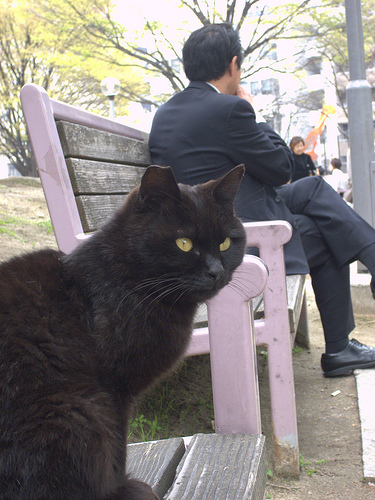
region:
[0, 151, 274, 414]
Black cat with green eyes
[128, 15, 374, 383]
Man in a suit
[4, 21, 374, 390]
Main sitting on a bench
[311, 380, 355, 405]
Cigarette butt on the ground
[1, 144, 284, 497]
Cat sitting on wooden platform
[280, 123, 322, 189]
Woman wearing a black coat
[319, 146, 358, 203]
Woman wearing a white coat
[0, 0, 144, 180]
Tree with green leaves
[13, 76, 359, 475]
Pink bench at the park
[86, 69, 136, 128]
Clear street light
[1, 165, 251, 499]
cat sitting on bench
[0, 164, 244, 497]
large cat sitting on bench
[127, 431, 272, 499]
part of wooden bench where cat is sitting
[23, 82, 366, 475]
bench where man is sitting on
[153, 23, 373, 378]
man sitting on bench outside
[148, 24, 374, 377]
man wearing suit sitting on bench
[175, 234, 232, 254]
green eyes of cat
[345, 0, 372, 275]
long gray pole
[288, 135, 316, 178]
woman wearing black in the distance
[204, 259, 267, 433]
pink arm of the bench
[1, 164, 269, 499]
a black cat sitting atop a pink and grey bench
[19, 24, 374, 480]
a businessman sitting on a pink and grey park bench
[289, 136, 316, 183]
a woman with a black top standing in the distance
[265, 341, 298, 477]
pink painted bench leg with rusty bottom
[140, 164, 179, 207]
black right ear is alert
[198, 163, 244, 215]
black left ear is alert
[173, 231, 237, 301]
cat face with intently looking eyes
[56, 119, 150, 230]
back of park bench looks weathered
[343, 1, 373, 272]
tall grey metal lamp post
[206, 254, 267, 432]
pale pink metal park bench arm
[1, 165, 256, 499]
a black cat on a bench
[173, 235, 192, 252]
eye of a cat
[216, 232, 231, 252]
eye of a cat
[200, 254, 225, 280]
nose of a cat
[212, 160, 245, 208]
ear of a black cat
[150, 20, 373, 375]
a man sitting at a bench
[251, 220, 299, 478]
pink wooden post on a bench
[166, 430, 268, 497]
wooden slat on bench seat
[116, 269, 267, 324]
a cat's whiskers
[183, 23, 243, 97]
back of a man's head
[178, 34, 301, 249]
A man sitting on the bench.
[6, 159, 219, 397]
Black cat sitting on the bench.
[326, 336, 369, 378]
The man has black shoes.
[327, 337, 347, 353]
The man is wearing black socks.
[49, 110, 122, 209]
The back part of bench is wood.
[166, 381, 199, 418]
Grass and dirt under the bench.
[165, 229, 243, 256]
The cat has green eyes.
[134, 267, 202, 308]
The cat has long whiskers.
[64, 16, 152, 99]
The tree has green leaves.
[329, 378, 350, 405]
Cigarette bud on ground